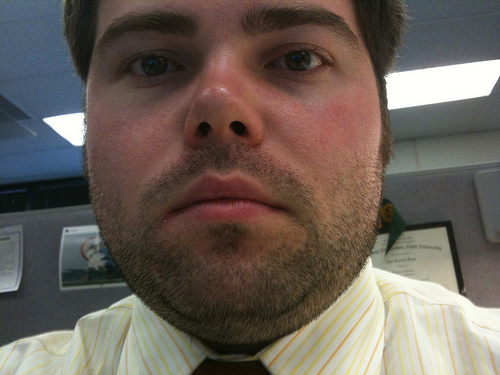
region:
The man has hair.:
[58, 0, 400, 351]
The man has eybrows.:
[54, 0, 425, 338]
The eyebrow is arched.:
[91, 7, 203, 60]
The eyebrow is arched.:
[237, 0, 373, 52]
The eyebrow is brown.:
[88, 4, 203, 61]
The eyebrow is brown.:
[238, 0, 364, 51]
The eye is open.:
[108, 39, 197, 91]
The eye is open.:
[249, 33, 345, 89]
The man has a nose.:
[56, 0, 401, 353]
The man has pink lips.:
[55, 0, 415, 353]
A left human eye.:
[237, 0, 364, 92]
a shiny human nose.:
[171, 57, 279, 160]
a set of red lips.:
[129, 138, 357, 260]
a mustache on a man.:
[133, 140, 324, 247]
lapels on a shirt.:
[77, 246, 397, 373]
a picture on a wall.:
[53, 222, 140, 299]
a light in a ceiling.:
[374, 20, 496, 122]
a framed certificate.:
[364, 205, 469, 304]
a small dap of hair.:
[195, 215, 268, 263]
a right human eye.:
[91, 28, 212, 124]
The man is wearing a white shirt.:
[15, 295, 493, 374]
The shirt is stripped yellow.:
[1, 285, 494, 367]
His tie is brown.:
[183, 356, 276, 373]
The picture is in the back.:
[55, 220, 121, 290]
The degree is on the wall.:
[369, 212, 477, 296]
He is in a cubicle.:
[5, 3, 477, 371]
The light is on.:
[375, 61, 497, 114]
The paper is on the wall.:
[0, 220, 24, 299]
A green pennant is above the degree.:
[371, 200, 414, 258]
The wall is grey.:
[3, 214, 498, 268]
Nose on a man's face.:
[185, 52, 264, 147]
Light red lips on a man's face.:
[162, 167, 292, 222]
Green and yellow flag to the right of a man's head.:
[380, 197, 407, 256]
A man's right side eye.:
[119, 50, 183, 82]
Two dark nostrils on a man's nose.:
[193, 118, 248, 137]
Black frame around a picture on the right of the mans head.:
[376, 219, 466, 298]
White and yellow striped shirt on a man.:
[3, 257, 496, 372]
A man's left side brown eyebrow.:
[238, 3, 360, 50]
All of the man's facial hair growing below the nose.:
[85, 143, 384, 343]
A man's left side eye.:
[258, 45, 334, 73]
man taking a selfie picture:
[0, 0, 497, 373]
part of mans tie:
[196, 354, 271, 374]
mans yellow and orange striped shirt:
[1, 253, 498, 373]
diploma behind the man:
[372, 218, 467, 297]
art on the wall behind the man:
[57, 225, 128, 290]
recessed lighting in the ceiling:
[380, 57, 499, 109]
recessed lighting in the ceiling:
[40, 110, 83, 150]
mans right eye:
[123, 49, 180, 83]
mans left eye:
[264, 47, 325, 74]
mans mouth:
[156, 169, 288, 221]